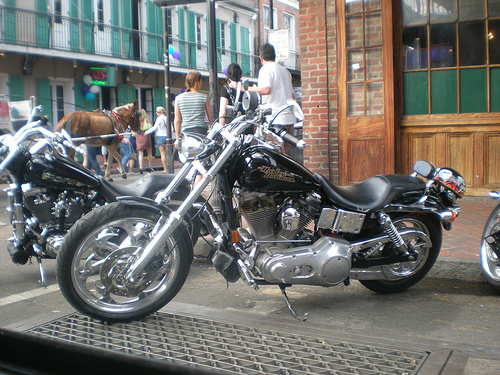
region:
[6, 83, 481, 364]
motorcycles parked on the street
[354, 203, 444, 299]
the rear wheel of a motorcycle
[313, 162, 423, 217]
the seat of a motorcycle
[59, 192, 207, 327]
the front wheel of a motorcycle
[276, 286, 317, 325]
the kickstand of a motorcycle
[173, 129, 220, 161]
the headlight of a motorcycle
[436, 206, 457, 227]
the taillight of a motorcycle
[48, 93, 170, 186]
a woman guiding a horse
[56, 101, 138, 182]
a brown and white horse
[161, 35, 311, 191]
three people on the side of a street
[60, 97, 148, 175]
brown horse with white mane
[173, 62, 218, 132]
blond woman with white and blue striped shirt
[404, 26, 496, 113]
wooden window with green panes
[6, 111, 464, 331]
two black and chrome motorcycles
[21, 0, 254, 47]
doors on upper floor of hotel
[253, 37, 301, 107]
black haired man in white shirt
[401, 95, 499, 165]
wooden panels below windows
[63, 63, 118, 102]
four balloons next to sign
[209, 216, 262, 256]
orange reflector on motorcycle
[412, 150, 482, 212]
black and orange helmet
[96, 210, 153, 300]
chrome rim on motorbike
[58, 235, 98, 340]
black tire outside rim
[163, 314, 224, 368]
motorbike on metal grate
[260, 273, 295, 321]
motorbike has kick stand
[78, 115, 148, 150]
brown pony in background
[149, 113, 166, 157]
person wearing blue shorts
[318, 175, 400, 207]
black seat on motorbike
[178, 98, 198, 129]
woman wearing striped shirt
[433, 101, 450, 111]
green window in background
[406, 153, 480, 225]
black and silver helmet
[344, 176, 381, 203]
the seat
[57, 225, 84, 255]
the front tire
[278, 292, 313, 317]
the kick stand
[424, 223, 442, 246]
back tire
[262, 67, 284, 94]
man wearing a white shirt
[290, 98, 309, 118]
a mirror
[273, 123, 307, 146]
the handle bars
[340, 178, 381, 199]
the seat is black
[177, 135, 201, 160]
the headlights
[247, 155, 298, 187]
brand of the motorcycle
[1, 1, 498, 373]
Motorcycle parked infront of a brick building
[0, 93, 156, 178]
Horse attached to a buggy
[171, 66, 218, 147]
Woman in a stripped shirt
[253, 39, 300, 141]
Man in a short sleeved white shirt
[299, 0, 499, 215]
Brick building with wood window frames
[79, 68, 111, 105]
Balloons attached to a building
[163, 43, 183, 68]
Blue, purple and white balloons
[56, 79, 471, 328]
Black Harley Davidson with chrome detailing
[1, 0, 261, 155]
Two story building with green shutters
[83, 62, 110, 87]
Neon sign on the front of a building